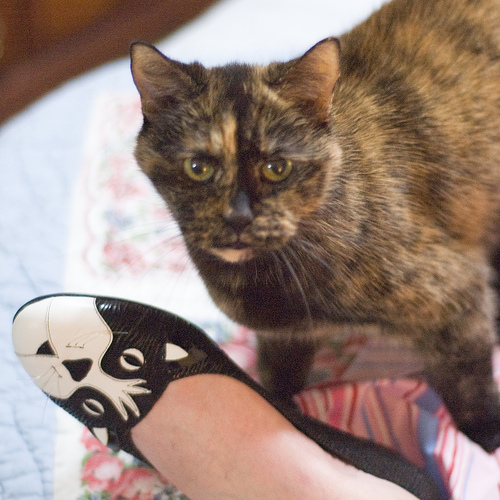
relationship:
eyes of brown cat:
[179, 153, 296, 188] [128, 0, 500, 456]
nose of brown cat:
[222, 191, 252, 233] [128, 0, 500, 456]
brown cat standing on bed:
[128, 0, 500, 456] [2, 4, 498, 498]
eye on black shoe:
[107, 342, 148, 365] [8, 293, 441, 500]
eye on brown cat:
[260, 159, 295, 183] [128, 0, 500, 456]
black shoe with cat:
[8, 293, 441, 500] [11, 293, 191, 453]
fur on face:
[237, 100, 330, 200] [128, 34, 345, 266]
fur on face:
[181, 100, 235, 182] [128, 34, 345, 266]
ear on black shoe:
[155, 335, 196, 367] [8, 293, 441, 500]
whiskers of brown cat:
[283, 241, 363, 298] [128, 0, 500, 456]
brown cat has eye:
[128, 0, 500, 456] [262, 159, 293, 182]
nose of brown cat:
[220, 192, 256, 233] [128, 0, 500, 456]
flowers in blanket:
[80, 435, 165, 500] [4, 2, 498, 498]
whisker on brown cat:
[282, 244, 322, 307] [128, 0, 500, 456]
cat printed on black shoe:
[8, 289, 190, 452] [8, 293, 441, 500]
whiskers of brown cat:
[272, 207, 375, 353] [128, 0, 500, 456]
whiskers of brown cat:
[143, 229, 204, 281] [128, 0, 500, 456]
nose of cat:
[220, 192, 256, 233] [121, 2, 499, 397]